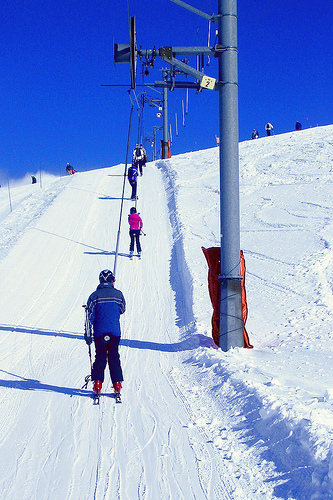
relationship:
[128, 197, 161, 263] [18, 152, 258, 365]
person standing on snow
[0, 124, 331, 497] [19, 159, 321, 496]
snow on ground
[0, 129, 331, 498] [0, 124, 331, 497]
tracks on snow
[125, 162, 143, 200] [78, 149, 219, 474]
person on hill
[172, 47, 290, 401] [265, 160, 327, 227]
poles in snow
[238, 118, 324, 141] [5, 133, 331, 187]
people on hill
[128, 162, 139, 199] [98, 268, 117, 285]
person with helmet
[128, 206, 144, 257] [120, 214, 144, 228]
person with jacket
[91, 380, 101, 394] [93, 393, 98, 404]
boot on ski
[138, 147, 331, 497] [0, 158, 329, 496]
snow bank on lift trail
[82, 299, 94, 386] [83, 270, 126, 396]
ski poles of people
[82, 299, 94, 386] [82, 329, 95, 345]
ski poles in hands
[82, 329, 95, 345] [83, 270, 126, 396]
hands of people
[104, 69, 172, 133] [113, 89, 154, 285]
ski tow for lift